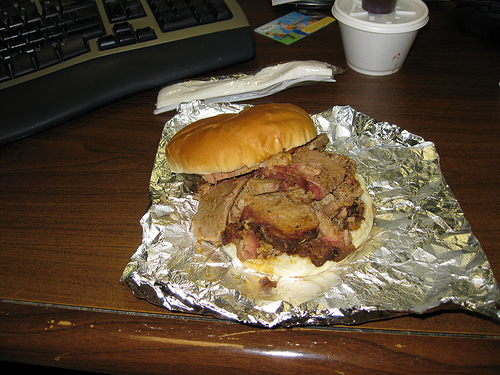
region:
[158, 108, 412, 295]
A sandwich on the aluminum foil.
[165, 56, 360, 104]
A plastic fork on the table.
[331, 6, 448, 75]
A white container with the lid on top.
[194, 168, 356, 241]
Beef is in the middle of the sandwich.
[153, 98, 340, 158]
A bun on the foil.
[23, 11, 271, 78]
A keyboard is on the table.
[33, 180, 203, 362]
The table is wooden.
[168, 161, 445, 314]
The sandwich is sitting in the aluminum foil.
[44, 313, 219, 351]
The table has scratches and marks.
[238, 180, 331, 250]
The meat on the sandwich is beef.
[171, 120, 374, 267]
a barbecue sandwich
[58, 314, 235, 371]
the scuffed edge of a brown wood table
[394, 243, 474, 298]
reflective silver aluminum foil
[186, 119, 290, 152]
the browned top bun of a sandwich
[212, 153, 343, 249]
slices of barbecued beef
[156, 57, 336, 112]
a white paper napkin and plasticware surrounded in plastic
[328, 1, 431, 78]
a white styrofoam cup with a plastic lid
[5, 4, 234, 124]
a black and beige keyboard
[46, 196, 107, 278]
a striped grain wooden table top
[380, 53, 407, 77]
barbecue sauce on the side of a styrofoam cup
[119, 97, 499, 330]
Sandwich on aluminum foil wrapper.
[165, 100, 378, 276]
Barbecue meat on hamburger bun.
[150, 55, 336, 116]
Plastic silverware and napkin in plastic wrap.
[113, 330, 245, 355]
Scratch on edge of tabletop.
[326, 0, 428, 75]
White styrofoam cup with lid.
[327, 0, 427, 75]
Styrofoam cup containing barbecue sauce.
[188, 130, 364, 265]
Delicious-looking barbecue meat in sandwich.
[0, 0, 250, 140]
Black computer keyboard.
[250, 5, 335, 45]
Colorful card with cartoon figures.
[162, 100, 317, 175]
Top of sandwich bun.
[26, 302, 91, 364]
scratched artificial wood desk top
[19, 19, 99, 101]
black and silver keys on keyboard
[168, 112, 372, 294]
messy chopped meat on a bun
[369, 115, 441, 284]
wrinkled metallic silver foil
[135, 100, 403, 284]
sandwich in unwrapped foil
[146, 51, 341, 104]
fork and napkin wrapped up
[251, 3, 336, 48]
business card on desk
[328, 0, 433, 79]
styrofoam container with plastic lid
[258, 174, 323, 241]
slow cooked sliced up mear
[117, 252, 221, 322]
corner of foil wrapper folded up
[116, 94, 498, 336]
this is aluminum foil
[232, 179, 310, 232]
this is brown port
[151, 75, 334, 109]
this is a white napkin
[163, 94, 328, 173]
this is a top bun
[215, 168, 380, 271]
this is the bottom bun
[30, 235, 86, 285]
this is brown wood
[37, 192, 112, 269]
this is the color brown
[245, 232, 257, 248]
this is the color red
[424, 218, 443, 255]
this is the color gray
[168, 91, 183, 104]
this is the color white